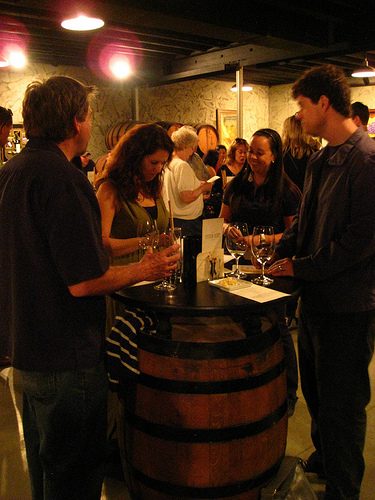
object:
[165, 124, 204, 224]
people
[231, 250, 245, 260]
wine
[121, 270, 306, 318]
table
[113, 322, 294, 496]
barrel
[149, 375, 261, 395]
rings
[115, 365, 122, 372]
black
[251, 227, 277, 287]
wine glasses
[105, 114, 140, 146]
barrels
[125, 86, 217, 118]
wall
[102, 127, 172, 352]
woman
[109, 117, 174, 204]
long hair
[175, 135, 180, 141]
white hair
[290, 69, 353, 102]
brown hair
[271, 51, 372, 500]
man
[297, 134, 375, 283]
jacket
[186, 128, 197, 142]
gray hair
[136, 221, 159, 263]
wine glass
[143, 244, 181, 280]
hand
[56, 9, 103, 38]
lights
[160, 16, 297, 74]
ceiling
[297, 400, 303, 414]
ground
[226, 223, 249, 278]
glass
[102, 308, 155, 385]
striped shirt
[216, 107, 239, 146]
painting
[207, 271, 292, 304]
menu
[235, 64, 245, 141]
support beam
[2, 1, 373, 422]
room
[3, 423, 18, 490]
concrete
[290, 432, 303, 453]
floor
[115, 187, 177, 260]
shirt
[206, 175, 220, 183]
menu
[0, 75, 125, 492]
man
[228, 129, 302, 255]
lady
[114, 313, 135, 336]
striped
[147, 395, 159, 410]
wooden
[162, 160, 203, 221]
white shirt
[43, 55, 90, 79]
overhead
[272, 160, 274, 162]
earring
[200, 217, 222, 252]
paper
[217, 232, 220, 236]
words